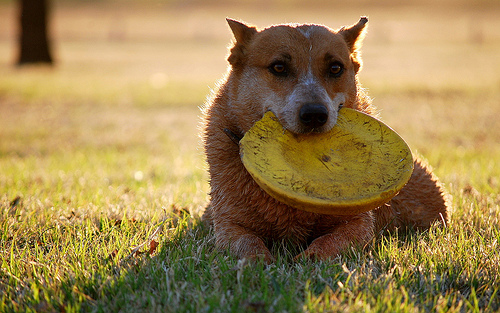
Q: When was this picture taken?
A: During the day.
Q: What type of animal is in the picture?
A: A dog.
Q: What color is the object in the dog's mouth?
A: Yellow.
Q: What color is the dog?
A: Brown.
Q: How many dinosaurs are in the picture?
A: Zero.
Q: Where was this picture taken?
A: In the grass.